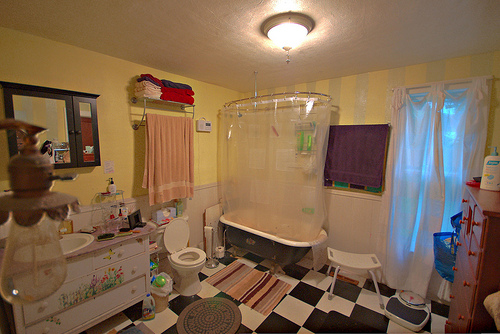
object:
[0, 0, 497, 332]
bathroom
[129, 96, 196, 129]
rack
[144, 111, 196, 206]
towel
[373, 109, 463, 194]
window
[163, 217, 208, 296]
toilet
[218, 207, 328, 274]
tub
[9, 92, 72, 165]
mirror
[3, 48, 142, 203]
wall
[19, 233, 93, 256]
sink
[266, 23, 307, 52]
light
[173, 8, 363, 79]
ceiling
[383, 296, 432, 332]
scale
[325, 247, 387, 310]
chair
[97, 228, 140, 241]
lotion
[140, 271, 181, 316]
trash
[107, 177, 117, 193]
bottle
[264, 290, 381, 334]
floor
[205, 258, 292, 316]
mat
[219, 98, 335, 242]
curtain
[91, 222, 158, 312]
counter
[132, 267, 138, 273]
knob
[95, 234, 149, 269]
drawer